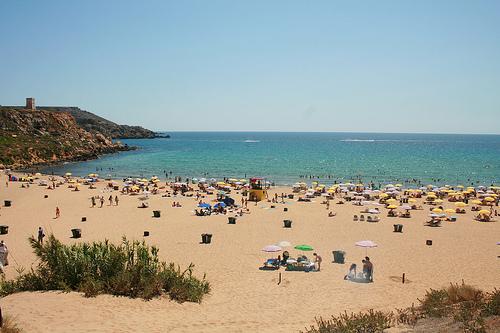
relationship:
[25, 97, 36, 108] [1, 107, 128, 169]
building on hill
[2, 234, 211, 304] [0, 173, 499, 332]
shrub on beach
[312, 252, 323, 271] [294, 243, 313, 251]
person under umbrella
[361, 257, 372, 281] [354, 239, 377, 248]
person under umbrella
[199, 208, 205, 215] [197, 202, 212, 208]
person under umbrella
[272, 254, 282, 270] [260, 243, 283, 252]
person under umbrella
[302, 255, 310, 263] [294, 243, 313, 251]
person under umbrella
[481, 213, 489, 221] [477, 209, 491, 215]
person under umbrella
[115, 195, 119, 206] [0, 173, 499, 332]
person walking on beach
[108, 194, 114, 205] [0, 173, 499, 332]
person walking on beach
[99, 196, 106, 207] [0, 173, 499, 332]
person walking on beach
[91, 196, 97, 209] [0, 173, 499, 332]
person walking on beach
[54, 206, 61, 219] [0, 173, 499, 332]
person walking on beach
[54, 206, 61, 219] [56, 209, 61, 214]
person wearing shirt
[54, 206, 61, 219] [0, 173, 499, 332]
person on beach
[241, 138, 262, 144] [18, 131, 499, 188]
wave in ocean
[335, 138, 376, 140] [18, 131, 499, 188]
wave in ocean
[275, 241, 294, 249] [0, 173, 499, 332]
umbrella on beach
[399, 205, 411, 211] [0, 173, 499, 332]
umbrella on beach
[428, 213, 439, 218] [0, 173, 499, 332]
umbrella on beach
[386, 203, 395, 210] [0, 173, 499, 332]
umbrella on beach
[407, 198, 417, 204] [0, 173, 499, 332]
umbrella on beach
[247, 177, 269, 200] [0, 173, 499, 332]
lifeguard stand on beach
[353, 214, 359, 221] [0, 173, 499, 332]
chair on beach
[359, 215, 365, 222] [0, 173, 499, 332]
chair on beach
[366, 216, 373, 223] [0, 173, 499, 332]
chair on beach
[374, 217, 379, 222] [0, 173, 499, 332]
chair on beach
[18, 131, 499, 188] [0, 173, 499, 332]
ocean by beach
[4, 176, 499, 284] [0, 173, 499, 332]
crowd on beach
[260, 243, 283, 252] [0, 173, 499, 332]
umbrella on beach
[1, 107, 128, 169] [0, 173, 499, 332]
hill near beach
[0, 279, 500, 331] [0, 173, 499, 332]
dune near beach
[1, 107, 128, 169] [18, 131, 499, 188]
hill by ocean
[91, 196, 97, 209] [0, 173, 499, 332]
person on beach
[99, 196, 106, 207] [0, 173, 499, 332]
person on beach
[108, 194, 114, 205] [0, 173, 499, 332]
person on beach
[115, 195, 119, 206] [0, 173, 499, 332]
person on beach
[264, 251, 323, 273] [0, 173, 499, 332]
group on beach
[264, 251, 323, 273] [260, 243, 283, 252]
group with umbrella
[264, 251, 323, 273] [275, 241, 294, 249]
group with umbrella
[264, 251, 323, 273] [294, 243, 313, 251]
group with umbrella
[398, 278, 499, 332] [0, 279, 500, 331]
bush on dune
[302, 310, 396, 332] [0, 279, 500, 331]
bush on dune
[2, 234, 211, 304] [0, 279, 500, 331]
shrub on dune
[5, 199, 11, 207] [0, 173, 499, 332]
trash can on beach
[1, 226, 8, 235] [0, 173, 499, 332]
trash can on beach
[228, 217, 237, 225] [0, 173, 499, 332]
trash can on beach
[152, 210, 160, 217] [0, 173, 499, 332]
trash can on beach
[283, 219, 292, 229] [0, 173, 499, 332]
trash can on beach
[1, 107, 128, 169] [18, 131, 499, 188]
hill overlooking ocean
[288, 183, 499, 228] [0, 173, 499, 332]
umbrellas on beach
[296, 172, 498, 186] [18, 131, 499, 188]
people in ocean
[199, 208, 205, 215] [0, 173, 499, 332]
person on beach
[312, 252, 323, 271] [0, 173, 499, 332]
person on beach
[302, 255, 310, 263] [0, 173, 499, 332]
person on beach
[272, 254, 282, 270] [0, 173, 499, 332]
person on beach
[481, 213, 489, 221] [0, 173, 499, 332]
person on beach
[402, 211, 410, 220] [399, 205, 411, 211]
person under umbrella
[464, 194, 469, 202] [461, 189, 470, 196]
person under umbrella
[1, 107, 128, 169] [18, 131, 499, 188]
hill surrounded by ocean